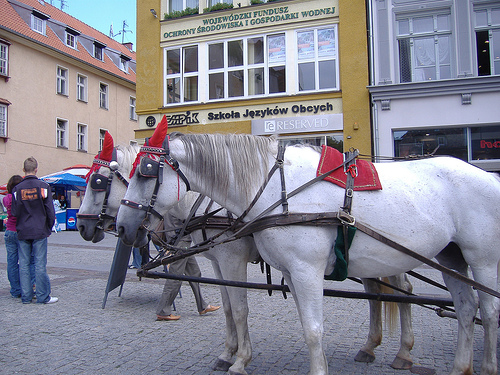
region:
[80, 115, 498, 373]
two beautiful white horses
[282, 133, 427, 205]
red horse blanket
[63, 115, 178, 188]
two red tassels for horses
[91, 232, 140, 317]
stand up street advertisement sign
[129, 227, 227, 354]
bottom half of man waking on sidewalk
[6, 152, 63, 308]
man and woman standing on sidewalk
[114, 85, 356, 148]
advertisement of store front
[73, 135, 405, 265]
bridals and reigns on horses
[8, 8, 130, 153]
windows in a apartment building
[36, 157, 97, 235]
umbrellas with concessions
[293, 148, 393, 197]
Maroon and gold horse blanket.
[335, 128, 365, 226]
Silver buckles on a bridle.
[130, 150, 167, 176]
Black eye covering with silver button.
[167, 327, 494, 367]
Eight white horse legs.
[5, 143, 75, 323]
Boy and girl standing on street.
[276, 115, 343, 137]
Silver sign with white letters.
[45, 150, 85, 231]
Pepsi-cola umbrella stand.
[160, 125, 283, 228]
A grayish brown horses mane.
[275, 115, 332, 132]
White letters that say reserved.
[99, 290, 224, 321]
A pair of brown dress shoes.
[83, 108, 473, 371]
two large white horses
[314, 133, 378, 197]
red blanket on horses back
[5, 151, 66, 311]
two people standing on sidewalk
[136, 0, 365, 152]
building painted yellow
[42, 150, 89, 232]
blue pepsi umbrella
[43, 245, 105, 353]
cobblestone street and sidewalk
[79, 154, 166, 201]
black blinders on horses eyes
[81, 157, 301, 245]
brown and black reigns on horses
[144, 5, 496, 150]
storefront buildings lining street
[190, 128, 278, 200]
very little brown horse mane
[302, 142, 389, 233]
The horse has a red blanket on its back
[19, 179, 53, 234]
The man is wearing a blue and white and orange jacket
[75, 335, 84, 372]
The brick is gray and old and worn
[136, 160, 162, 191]
The blinders the horse is wearing are black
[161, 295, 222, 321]
The woman's shoes are brown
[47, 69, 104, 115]
The windows of the building have a white frame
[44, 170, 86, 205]
The umbrella of the stand is blue in color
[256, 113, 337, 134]
This sign is grey and says "RESERVED"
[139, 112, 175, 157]
The horse's head-dress is red in color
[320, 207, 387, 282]
The horse's straps to keep the horse contained are brown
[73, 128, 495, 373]
Two white horses standing in street.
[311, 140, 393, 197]
Red blanket under horse's girth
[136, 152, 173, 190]
Side blinders on horse.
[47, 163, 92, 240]
Food stand with blue umbrella.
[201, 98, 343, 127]
Name of shop written in black.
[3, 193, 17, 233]
Woman dressed in pink top.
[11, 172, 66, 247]
Man dressed in navy blue jacket.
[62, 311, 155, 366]
An old cobblestone street.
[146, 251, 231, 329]
Bottom part of a person walking by horses.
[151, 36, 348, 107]
Second floor windows on front of building.